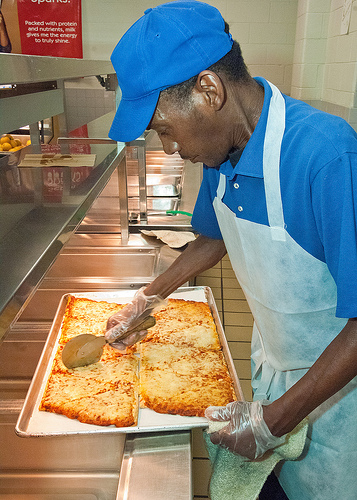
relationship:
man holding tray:
[106, 3, 356, 500] [13, 285, 248, 436]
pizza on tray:
[44, 296, 235, 432] [13, 285, 248, 436]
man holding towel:
[106, 3, 356, 500] [209, 412, 310, 499]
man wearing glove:
[106, 3, 356, 500] [205, 403, 283, 463]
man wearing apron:
[106, 3, 356, 500] [211, 80, 357, 497]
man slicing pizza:
[106, 3, 356, 500] [44, 296, 235, 432]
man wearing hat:
[106, 3, 356, 500] [105, 3, 232, 144]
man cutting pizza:
[106, 3, 356, 500] [44, 296, 235, 432]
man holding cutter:
[106, 3, 356, 500] [62, 315, 158, 369]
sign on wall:
[17, 1, 80, 61] [2, 1, 357, 143]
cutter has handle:
[62, 315, 158, 369] [110, 315, 155, 342]